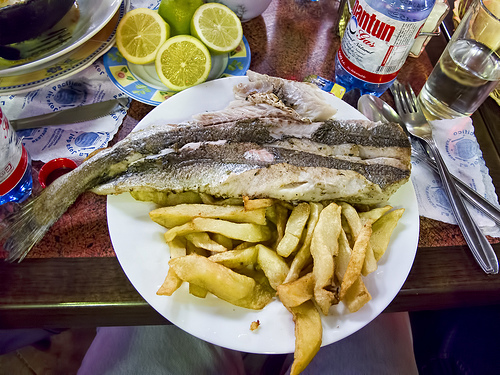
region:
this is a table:
[274, 18, 305, 57]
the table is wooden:
[51, 240, 81, 286]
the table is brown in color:
[70, 218, 91, 288]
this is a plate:
[120, 198, 150, 243]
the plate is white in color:
[129, 218, 143, 252]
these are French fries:
[168, 199, 368, 310]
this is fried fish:
[182, 115, 407, 192]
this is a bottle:
[349, 5, 393, 70]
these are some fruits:
[113, 2, 252, 78]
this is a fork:
[401, 88, 485, 240]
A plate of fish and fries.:
[5, 71, 421, 372]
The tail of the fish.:
[6, 145, 108, 263]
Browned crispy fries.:
[148, 196, 402, 371]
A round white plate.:
[105, 74, 420, 354]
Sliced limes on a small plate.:
[101, 16, 248, 106]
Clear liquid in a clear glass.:
[414, 3, 498, 135]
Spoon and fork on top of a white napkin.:
[357, 85, 499, 275]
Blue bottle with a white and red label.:
[331, 0, 433, 99]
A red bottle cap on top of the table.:
[35, 156, 78, 189]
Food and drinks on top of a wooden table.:
[1, 0, 499, 374]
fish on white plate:
[9, 101, 410, 201]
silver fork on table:
[391, 84, 494, 284]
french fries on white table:
[145, 201, 412, 356]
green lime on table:
[190, 4, 248, 52]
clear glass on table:
[422, 3, 498, 123]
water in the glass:
[423, 39, 495, 120]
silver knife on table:
[10, 95, 125, 130]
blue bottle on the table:
[335, 0, 436, 98]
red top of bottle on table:
[37, 155, 76, 186]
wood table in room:
[275, 22, 327, 63]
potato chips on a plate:
[196, 256, 243, 292]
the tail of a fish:
[18, 201, 60, 244]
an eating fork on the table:
[400, 93, 416, 113]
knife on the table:
[33, 114, 84, 125]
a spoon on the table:
[466, 184, 480, 206]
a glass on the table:
[463, 28, 487, 83]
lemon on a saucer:
[164, 43, 199, 75]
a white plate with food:
[201, 315, 233, 336]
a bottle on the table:
[369, 15, 391, 81]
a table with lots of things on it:
[442, 265, 469, 295]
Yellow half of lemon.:
[162, 33, 193, 93]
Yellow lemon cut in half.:
[126, 44, 141, 60]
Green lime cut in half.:
[195, 8, 251, 57]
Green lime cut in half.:
[166, 7, 188, 27]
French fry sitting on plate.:
[189, 258, 282, 341]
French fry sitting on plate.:
[269, 255, 317, 335]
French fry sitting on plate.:
[349, 244, 363, 263]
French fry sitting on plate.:
[173, 215, 229, 234]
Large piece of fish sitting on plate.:
[90, 141, 392, 191]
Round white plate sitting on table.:
[130, 97, 457, 344]